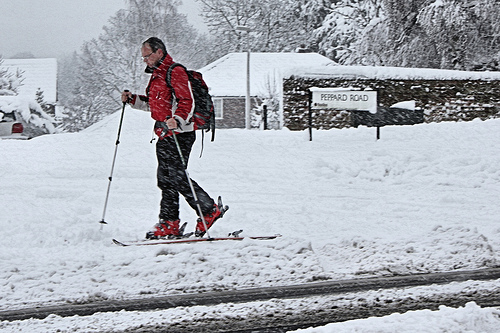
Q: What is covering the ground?
A: Snow.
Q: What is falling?
A: Snow.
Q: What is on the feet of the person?
A: Skis.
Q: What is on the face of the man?
A: Glasses.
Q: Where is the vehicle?
A: Left side toward the top.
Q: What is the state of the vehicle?
A: Parked.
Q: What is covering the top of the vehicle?
A: Snow.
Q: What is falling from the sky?
A: Snow.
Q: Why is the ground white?
A: It's snowing.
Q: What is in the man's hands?
A: Ski poles.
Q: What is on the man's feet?
A: Ski boots.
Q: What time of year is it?
A: Winter.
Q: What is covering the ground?
A: Snow.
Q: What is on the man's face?
A: Glasses.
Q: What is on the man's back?
A: A backpack.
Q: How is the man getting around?
A: On skis.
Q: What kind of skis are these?
A: Cross country skis.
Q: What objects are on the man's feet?
A: Skis.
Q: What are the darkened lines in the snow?
A: Tire tracks.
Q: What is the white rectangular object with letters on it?
A: A sign.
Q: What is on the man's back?
A: A backpack.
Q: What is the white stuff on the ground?
A: Snow.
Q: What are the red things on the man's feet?
A: Ski boots.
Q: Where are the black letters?
A: On the white sign.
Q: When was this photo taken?
A: In the winter.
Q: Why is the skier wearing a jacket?
A: Because it is cold.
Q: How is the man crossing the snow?
A: By skiing.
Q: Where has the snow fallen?
A: On the ground.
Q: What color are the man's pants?
A: Black.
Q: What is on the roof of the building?
A: Snow.